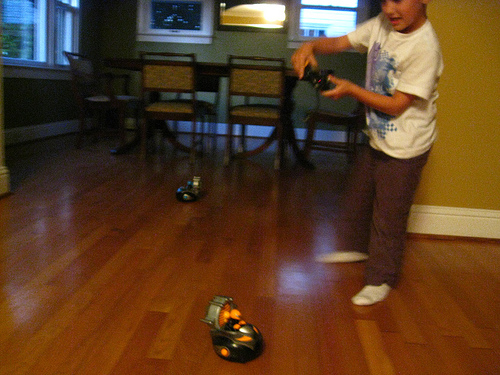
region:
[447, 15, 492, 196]
tan wall in living room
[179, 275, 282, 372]
black and orange radio controlled toy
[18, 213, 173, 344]
tan hardwood floor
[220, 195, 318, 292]
tan hardwood floor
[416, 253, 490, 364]
tan hardwood floor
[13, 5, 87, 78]
white window in dining area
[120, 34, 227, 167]
brown and tan chair in dining area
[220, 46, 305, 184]
brown and tan chair in dining area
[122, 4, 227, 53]
white window in dining area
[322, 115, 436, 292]
young boy wearing brown pants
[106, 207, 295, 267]
clean hard wood floor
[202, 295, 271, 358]
remote control race car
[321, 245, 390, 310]
small child in white socks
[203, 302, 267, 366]
yellow and black child's toy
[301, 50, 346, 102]
small child holding remote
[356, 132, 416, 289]
boy in long brown pants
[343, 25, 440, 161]
boy in white t-shirt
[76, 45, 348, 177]
dining room in apt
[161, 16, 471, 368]
boy playing with a remote control car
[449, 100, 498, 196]
taupe painted wall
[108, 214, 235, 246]
shiny brown wood floor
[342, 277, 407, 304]
white socks on boy's feet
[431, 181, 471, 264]
white base of gold wall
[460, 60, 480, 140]
solid gold wall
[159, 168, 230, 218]
blue and silver child's toy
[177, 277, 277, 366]
orange and gray remote controlled toy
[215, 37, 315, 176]
black and tan chairs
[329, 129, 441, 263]
boy wearing brown pants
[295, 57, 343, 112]
black remote in boy's hand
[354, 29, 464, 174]
white tee shirt with blue logo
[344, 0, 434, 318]
little boy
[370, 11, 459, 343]
little boy in white shirt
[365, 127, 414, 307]
brown pants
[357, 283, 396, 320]
white socks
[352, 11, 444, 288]
little boy in brown pants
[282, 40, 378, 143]
remote control in hands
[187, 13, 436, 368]
little boy operating a remote control device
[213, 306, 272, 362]
orange automobile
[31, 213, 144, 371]
brown wooden floor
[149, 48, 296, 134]
dining room table and chairs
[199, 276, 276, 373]
orange and black remote control car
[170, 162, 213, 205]
blue and silver remote control car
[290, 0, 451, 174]
boy holding a remote control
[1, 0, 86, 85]
window in the dining room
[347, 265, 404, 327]
white sock worn by the boy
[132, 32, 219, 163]
dining room chair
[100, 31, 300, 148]
dining room table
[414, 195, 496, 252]
white painted base board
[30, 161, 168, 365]
wood floor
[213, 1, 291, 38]
mirror hanging on the wall